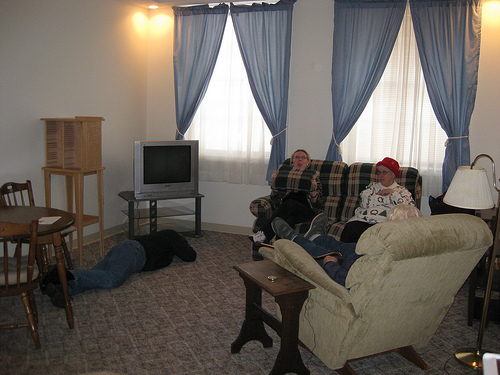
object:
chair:
[0, 219, 40, 317]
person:
[271, 204, 423, 287]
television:
[132, 139, 199, 200]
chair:
[248, 158, 422, 262]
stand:
[118, 190, 207, 240]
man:
[39, 229, 198, 310]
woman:
[339, 156, 415, 245]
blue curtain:
[407, 0, 483, 194]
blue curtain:
[325, 0, 409, 161]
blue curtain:
[229, 0, 295, 186]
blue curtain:
[170, 2, 228, 141]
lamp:
[149, 5, 159, 8]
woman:
[248, 148, 323, 247]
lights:
[483, 0, 497, 16]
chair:
[0, 179, 74, 275]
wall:
[0, 0, 152, 109]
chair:
[257, 213, 493, 375]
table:
[0, 206, 76, 329]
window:
[180, 10, 271, 157]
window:
[339, 0, 450, 168]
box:
[39, 116, 106, 172]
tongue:
[298, 164, 301, 165]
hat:
[375, 156, 400, 178]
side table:
[231, 259, 318, 374]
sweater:
[345, 180, 416, 224]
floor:
[87, 295, 225, 373]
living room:
[0, 0, 500, 375]